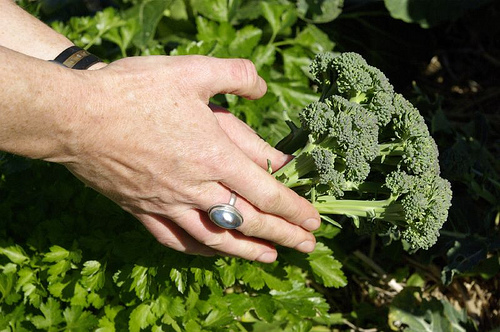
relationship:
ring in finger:
[203, 202, 259, 246] [152, 195, 339, 249]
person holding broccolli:
[42, 44, 305, 265] [316, 79, 451, 235]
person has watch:
[42, 44, 305, 265] [36, 40, 100, 107]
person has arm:
[67, 28, 288, 194] [7, 51, 199, 227]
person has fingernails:
[67, 28, 288, 194] [296, 200, 335, 262]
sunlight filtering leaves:
[249, 44, 309, 139] [273, 23, 329, 113]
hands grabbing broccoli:
[78, 55, 323, 263] [316, 79, 451, 235]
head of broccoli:
[333, 72, 423, 198] [316, 79, 451, 235]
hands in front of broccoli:
[42, 44, 305, 265] [268, 50, 456, 255]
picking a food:
[122, 44, 485, 267] [316, 79, 451, 235]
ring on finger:
[203, 202, 259, 246] [152, 195, 339, 249]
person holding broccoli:
[67, 28, 288, 194] [316, 79, 451, 235]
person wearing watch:
[67, 28, 288, 194] [36, 40, 100, 107]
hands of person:
[42, 44, 305, 265] [67, 28, 288, 194]